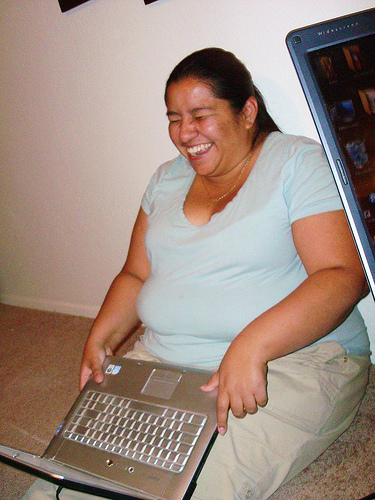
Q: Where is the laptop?
A: Woman's lap.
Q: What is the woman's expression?
A: Laughter.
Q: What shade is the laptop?
A: Light Blue.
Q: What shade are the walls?
A: White.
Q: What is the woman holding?
A: Laptop.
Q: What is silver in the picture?
A: Laptop.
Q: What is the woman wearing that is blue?
A: Shirt.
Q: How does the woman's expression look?
A: Happy.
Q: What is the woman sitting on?
A: Floor.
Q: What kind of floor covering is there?
A: Carpet.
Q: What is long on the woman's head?
A: Hair.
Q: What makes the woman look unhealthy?
A: Weight.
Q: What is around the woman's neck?
A: Necklace.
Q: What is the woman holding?
A: Laptop.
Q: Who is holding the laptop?
A: The woman.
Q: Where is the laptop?
A: In the woman's lap.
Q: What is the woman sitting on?
A: The floor.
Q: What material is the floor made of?
A: Carpet.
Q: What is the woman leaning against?
A: The wall.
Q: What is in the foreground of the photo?
A: Another laptop.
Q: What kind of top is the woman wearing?
A: A blue shirt.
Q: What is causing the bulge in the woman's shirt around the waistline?
A: Stomach fat.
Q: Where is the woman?
A: Sitting.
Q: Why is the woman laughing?
A: She's happy.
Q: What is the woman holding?
A: Laptop.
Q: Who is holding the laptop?
A: A woman.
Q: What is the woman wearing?
A: A shirt.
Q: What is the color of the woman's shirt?
A: Blue.